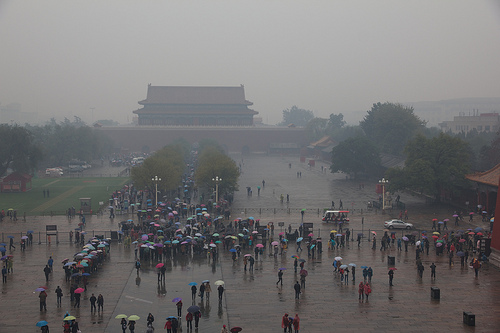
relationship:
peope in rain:
[2, 157, 498, 333] [2, 1, 499, 332]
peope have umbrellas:
[2, 157, 498, 333] [216, 279, 225, 286]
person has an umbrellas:
[333, 255, 342, 272] [216, 279, 225, 286]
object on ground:
[47, 224, 59, 235] [1, 150, 499, 331]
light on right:
[379, 178, 387, 185] [248, 1, 499, 332]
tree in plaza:
[332, 138, 384, 179] [194, 147, 431, 221]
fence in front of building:
[232, 207, 427, 217] [136, 84, 259, 125]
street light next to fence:
[210, 177, 223, 206] [232, 207, 427, 217]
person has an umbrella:
[333, 255, 342, 272] [255, 241, 265, 249]